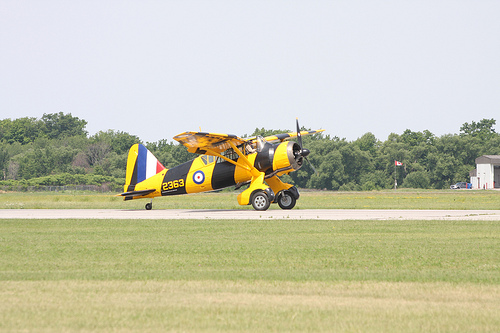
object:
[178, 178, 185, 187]
numbers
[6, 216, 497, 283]
grass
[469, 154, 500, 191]
structure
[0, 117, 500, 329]
airport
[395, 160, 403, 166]
canadian flag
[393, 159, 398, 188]
post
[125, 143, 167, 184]
tail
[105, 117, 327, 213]
plane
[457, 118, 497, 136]
trees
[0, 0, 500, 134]
clouds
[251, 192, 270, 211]
wheel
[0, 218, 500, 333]
ground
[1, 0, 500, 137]
sky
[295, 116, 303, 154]
propeller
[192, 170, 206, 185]
target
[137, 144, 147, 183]
stripes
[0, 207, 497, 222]
runway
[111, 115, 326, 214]
airplane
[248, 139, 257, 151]
windshield